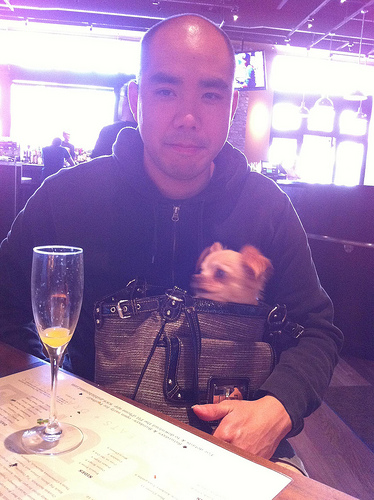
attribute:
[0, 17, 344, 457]
man — young, starring, asian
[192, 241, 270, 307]
dog — cute, small, puppy, tan, fluffy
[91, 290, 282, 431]
purse — designer bag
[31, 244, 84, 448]
glass — wine goblet, empty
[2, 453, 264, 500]
table — wood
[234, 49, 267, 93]
television — flat screen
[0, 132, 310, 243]
jacket — black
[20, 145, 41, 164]
bottles — alcohol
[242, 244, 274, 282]
ears — brown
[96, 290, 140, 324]
latch — silver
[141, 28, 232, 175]
mans face — round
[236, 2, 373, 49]
ceiling — open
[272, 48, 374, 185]
light glare — shining, wall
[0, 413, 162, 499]
menu — laminated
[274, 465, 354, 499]
table top — wooden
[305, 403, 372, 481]
floor — wooden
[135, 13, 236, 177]
his head — shaved